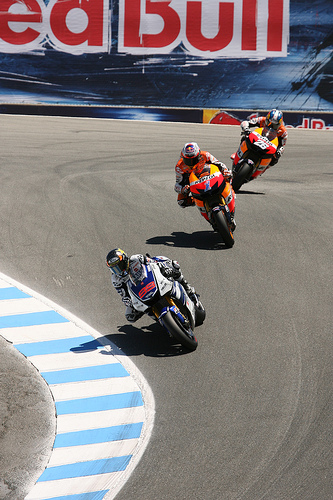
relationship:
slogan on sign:
[0, 0, 292, 60] [0, 0, 332, 129]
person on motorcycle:
[82, 250, 171, 291] [173, 170, 251, 220]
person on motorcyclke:
[240, 99, 301, 141] [51, 141, 249, 358]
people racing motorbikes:
[97, 85, 330, 346] [225, 125, 281, 191]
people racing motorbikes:
[97, 85, 330, 346] [183, 170, 247, 248]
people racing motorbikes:
[97, 85, 330, 346] [123, 259, 212, 351]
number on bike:
[136, 280, 154, 296] [128, 249, 206, 353]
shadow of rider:
[143, 221, 222, 253] [172, 137, 238, 251]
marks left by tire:
[63, 140, 203, 284] [232, 159, 252, 186]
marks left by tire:
[63, 140, 203, 284] [213, 203, 236, 241]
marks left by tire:
[63, 140, 203, 284] [159, 313, 198, 350]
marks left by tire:
[63, 140, 203, 284] [187, 290, 208, 320]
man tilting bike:
[174, 142, 202, 171] [178, 162, 240, 245]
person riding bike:
[98, 233, 207, 350] [126, 257, 210, 354]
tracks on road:
[232, 307, 324, 498] [13, 114, 330, 334]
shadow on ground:
[234, 183, 283, 207] [3, 113, 332, 496]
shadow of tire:
[234, 183, 283, 207] [229, 158, 251, 193]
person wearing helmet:
[105, 247, 206, 351] [105, 246, 131, 269]